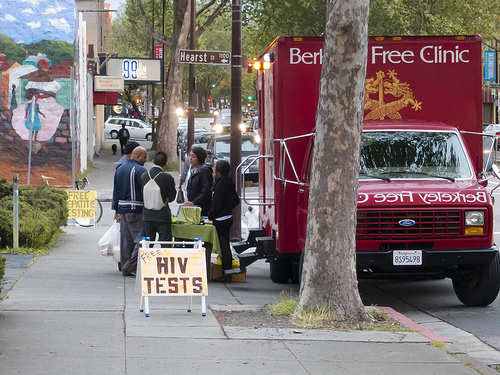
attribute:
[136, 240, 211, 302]
hiv test sign — sandwich board, yellow, free testing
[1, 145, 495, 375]
sidewalk — grey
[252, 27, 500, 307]
truck — red, berkeley free clinic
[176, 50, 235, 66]
street sign — brown, white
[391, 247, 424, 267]
license plate — white, california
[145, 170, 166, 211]
backpack — white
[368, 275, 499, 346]
street — asphalt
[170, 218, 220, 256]
tablecloth — green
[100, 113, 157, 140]
station wagon — white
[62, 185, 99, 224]
sign — set up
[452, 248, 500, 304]
tire — black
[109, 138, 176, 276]
people — inquiring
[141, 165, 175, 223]
sweater — black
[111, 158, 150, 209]
sweater — blue